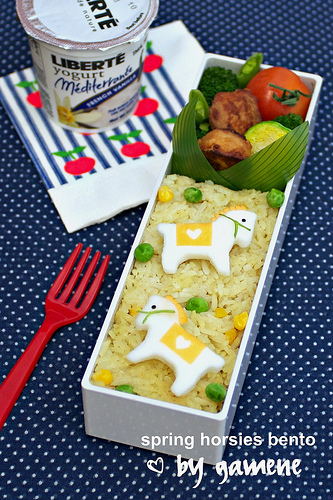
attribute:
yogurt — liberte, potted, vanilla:
[11, 1, 128, 80]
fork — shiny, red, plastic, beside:
[31, 250, 76, 371]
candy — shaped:
[135, 210, 267, 316]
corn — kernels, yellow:
[152, 178, 210, 237]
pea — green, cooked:
[131, 242, 197, 278]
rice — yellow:
[168, 256, 219, 281]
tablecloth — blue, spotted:
[10, 187, 61, 249]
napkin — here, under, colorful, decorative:
[40, 126, 172, 193]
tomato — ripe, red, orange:
[259, 60, 309, 101]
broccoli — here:
[203, 70, 257, 100]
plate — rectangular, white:
[170, 74, 282, 238]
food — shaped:
[166, 132, 254, 354]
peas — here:
[108, 242, 207, 325]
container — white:
[116, 402, 225, 447]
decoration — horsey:
[126, 262, 209, 380]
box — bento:
[55, 282, 259, 427]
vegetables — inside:
[196, 68, 309, 173]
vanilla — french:
[50, 42, 152, 156]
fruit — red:
[218, 72, 323, 145]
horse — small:
[126, 293, 253, 394]